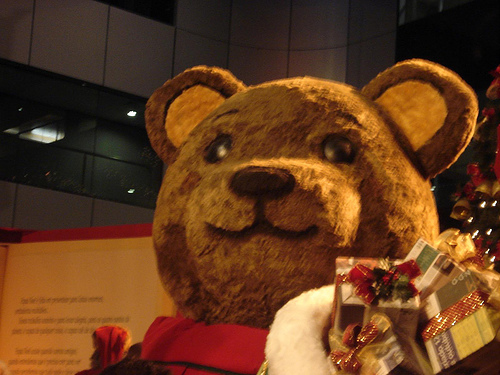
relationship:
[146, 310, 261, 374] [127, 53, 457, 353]
red collar on teddy bear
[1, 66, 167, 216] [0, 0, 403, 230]
windows on building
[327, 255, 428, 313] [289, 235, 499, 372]
bow on boxes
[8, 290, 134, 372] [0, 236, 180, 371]
writing on side of wall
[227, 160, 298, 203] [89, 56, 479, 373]
nose on teddybear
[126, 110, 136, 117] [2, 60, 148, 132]
light on ceiling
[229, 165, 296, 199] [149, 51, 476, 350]
nose on bear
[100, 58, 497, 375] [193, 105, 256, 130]
bear has eye brow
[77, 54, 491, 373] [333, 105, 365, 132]
bear has eyebrow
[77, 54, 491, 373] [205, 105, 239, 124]
bear has eyebrow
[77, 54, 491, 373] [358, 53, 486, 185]
bear has ear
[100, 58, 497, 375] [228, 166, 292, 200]
bear has nose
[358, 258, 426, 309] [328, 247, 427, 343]
bow on gift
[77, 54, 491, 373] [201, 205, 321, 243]
bear has mouth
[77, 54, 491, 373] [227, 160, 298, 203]
bear has nose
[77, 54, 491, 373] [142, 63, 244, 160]
bear has ear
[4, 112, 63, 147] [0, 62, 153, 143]
light in ceiling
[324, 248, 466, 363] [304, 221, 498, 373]
gifts in boxes